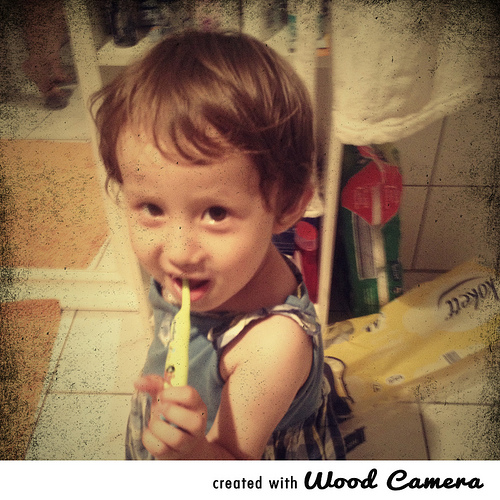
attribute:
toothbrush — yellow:
[156, 271, 213, 388]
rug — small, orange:
[6, 132, 123, 274]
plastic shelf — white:
[66, 0, 341, 324]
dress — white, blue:
[124, 256, 354, 458]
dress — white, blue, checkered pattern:
[149, 403, 359, 458]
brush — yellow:
[160, 275, 191, 390]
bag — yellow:
[315, 246, 498, 411]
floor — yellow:
[0, 278, 499, 460]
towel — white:
[311, 39, 425, 193]